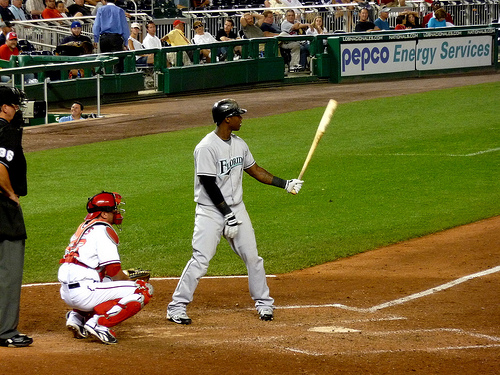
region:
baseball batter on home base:
[137, 56, 359, 324]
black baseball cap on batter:
[205, 88, 252, 120]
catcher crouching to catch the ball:
[56, 181, 143, 347]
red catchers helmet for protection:
[67, 178, 134, 218]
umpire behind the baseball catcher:
[2, 78, 44, 355]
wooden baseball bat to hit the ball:
[283, 80, 358, 212]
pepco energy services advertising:
[335, 24, 495, 84]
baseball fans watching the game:
[86, 9, 323, 47]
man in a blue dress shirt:
[95, 8, 156, 69]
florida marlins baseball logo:
[213, 152, 253, 187]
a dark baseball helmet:
[210, 99, 247, 121]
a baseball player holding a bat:
[168, 95, 335, 320]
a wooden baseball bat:
[300, 95, 337, 176]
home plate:
[308, 321, 358, 334]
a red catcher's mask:
[82, 190, 124, 222]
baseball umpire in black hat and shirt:
[0, 83, 32, 348]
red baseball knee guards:
[94, 284, 156, 339]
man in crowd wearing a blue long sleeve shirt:
[87, 1, 133, 52]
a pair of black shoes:
[0, 330, 32, 347]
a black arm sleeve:
[196, 169, 232, 216]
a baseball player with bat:
[169, 98, 336, 320]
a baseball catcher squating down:
[58, 193, 153, 340]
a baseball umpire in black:
[1, 86, 31, 346]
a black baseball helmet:
[212, 98, 247, 118]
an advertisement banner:
[337, 40, 490, 78]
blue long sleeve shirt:
[91, 8, 129, 39]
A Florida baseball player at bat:
[195, 99, 272, 321]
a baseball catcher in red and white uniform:
[71, 193, 151, 337]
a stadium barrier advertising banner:
[337, 33, 492, 68]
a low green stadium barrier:
[16, 50, 326, 81]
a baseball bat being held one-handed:
[290, 97, 337, 193]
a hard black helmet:
[206, 97, 248, 122]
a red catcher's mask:
[106, 190, 130, 230]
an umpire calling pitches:
[0, 81, 38, 348]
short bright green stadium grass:
[42, 83, 494, 273]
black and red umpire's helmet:
[76, 186, 139, 226]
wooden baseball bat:
[288, 90, 361, 180]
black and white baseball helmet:
[206, 94, 261, 131]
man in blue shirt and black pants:
[91, 2, 127, 74]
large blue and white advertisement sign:
[339, 33, 498, 74]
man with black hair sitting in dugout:
[45, 93, 109, 129]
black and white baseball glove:
[222, 211, 244, 241]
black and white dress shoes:
[0, 325, 39, 355]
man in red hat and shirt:
[0, 30, 25, 59]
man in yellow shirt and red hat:
[166, 17, 188, 57]